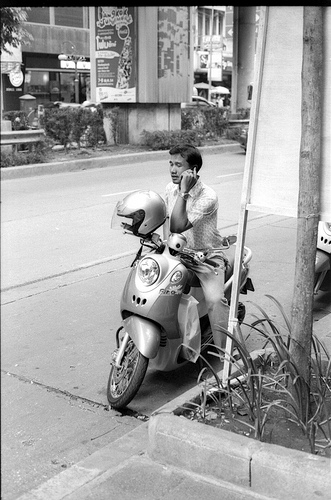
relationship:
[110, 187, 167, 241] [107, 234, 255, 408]
helmet on front of motorcycle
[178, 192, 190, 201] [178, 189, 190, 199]
watch on wrist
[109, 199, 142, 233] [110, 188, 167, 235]
shield on helmet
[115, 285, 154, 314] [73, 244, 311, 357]
holes on motorcycle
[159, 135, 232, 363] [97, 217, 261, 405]
guy sits on scooter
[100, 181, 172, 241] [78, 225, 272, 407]
helmet on scooter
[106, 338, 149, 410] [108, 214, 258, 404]
tire on scooter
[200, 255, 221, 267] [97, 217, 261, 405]
handle on scooter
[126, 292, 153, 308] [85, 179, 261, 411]
vent on scooter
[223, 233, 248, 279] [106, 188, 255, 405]
backseat on scooter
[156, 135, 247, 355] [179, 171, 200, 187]
guy holds cell phone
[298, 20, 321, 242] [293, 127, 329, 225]
tree has stump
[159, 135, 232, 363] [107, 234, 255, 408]
guy sits on motorcycle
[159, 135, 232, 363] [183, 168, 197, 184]
guy holds cell phone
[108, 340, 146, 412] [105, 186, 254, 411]
tire on front of scooter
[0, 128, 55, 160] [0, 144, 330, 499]
fence barrier on side of roadway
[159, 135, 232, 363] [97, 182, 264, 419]
guy on a scooter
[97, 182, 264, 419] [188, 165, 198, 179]
scooter talking on h cell phone